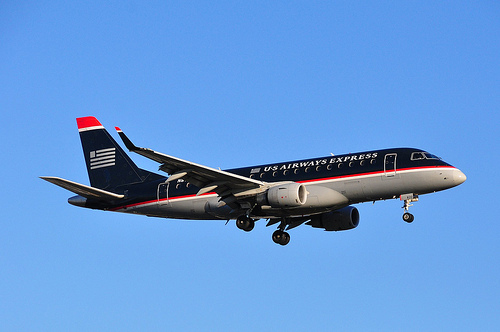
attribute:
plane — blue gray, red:
[64, 108, 473, 241]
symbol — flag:
[84, 150, 126, 172]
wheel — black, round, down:
[392, 193, 421, 221]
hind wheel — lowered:
[233, 208, 291, 249]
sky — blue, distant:
[262, 22, 354, 41]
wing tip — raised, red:
[116, 123, 137, 152]